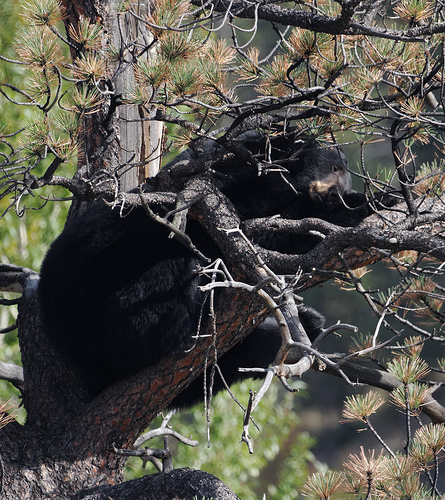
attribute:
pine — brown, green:
[66, 81, 106, 115]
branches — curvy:
[302, 61, 391, 180]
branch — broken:
[204, 262, 257, 428]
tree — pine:
[0, 1, 443, 498]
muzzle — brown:
[305, 155, 355, 200]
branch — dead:
[237, 355, 310, 459]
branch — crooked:
[248, 211, 439, 274]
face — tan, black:
[309, 154, 350, 206]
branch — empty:
[143, 193, 444, 425]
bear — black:
[34, 108, 365, 398]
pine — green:
[138, 29, 217, 90]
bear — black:
[37, 107, 412, 407]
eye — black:
[332, 161, 343, 174]